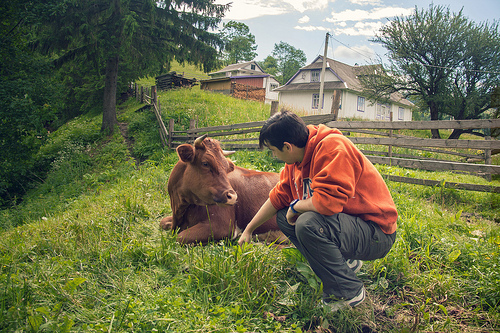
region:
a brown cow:
[163, 138, 288, 243]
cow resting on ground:
[165, 134, 289, 246]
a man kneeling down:
[235, 107, 398, 303]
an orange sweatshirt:
[260, 126, 402, 236]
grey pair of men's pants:
[268, 197, 396, 299]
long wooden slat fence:
[125, 78, 497, 203]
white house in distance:
[270, 56, 413, 125]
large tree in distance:
[23, 0, 229, 140]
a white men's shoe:
[322, 285, 364, 315]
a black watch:
[285, 196, 300, 211]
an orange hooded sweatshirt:
[267, 123, 398, 230]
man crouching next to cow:
[226, 105, 396, 310]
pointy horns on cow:
[191, 131, 208, 148]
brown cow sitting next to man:
[155, 131, 293, 245]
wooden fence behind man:
[123, 78, 498, 197]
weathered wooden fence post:
[166, 117, 176, 147]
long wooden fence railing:
[333, 115, 498, 138]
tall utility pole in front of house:
[317, 30, 331, 117]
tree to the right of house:
[355, 2, 499, 139]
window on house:
[356, 95, 366, 112]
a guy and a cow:
[145, 103, 415, 317]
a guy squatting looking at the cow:
[149, 100, 410, 320]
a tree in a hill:
[47, 2, 161, 147]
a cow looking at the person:
[155, 110, 405, 325]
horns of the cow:
[188, 127, 238, 160]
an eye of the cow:
[197, 155, 212, 170]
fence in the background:
[130, 80, 178, 150]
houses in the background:
[207, 20, 418, 110]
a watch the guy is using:
[286, 195, 297, 215]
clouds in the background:
[267, 0, 390, 22]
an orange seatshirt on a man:
[263, 119, 405, 231]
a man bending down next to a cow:
[236, 106, 407, 313]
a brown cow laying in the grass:
[158, 126, 290, 259]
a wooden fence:
[327, 107, 495, 179]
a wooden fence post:
[166, 114, 178, 148]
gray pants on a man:
[274, 203, 400, 303]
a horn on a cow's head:
[193, 126, 212, 152]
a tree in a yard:
[370, 1, 497, 151]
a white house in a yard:
[277, 43, 418, 136]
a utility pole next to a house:
[312, 29, 333, 110]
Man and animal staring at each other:
[150, 109, 400, 251]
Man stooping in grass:
[255, 108, 404, 311]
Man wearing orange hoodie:
[250, 110, 403, 240]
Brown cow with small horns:
[160, 130, 244, 247]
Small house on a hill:
[194, 51, 276, 116]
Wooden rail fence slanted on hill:
[140, 85, 176, 153]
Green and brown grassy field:
[367, 263, 498, 330]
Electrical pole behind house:
[310, 29, 339, 119]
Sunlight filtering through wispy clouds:
[240, 0, 385, 33]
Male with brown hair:
[252, 105, 319, 170]